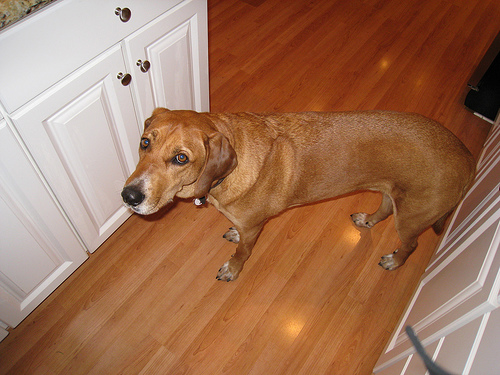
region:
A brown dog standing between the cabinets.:
[124, 105, 463, 285]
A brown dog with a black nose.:
[124, 105, 492, 289]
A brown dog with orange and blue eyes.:
[116, 105, 478, 287]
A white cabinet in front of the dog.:
[5, 22, 216, 251]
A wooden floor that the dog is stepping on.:
[220, 6, 453, 372]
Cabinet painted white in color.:
[1, 0, 237, 285]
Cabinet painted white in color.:
[412, 221, 495, 371]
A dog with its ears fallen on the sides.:
[124, 106, 466, 288]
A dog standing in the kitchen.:
[114, 104, 485, 294]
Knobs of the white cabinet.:
[100, 6, 156, 91]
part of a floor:
[280, 227, 333, 294]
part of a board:
[248, 265, 287, 324]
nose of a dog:
[118, 179, 148, 197]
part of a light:
[259, 280, 299, 360]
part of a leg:
[235, 210, 261, 252]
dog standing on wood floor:
[102, 89, 472, 309]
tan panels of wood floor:
[97, 247, 233, 369]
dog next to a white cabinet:
[90, 85, 248, 232]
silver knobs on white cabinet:
[100, 53, 165, 84]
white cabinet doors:
[40, 30, 244, 270]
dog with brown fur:
[103, 99, 490, 261]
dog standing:
[87, 72, 499, 348]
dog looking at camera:
[91, 83, 261, 233]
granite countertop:
[0, 4, 55, 17]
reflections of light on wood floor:
[242, 14, 457, 129]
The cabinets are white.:
[433, 243, 471, 345]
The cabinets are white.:
[411, 275, 480, 370]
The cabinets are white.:
[420, 257, 452, 355]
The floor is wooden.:
[193, 291, 274, 344]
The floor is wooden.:
[196, 306, 285, 362]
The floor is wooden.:
[159, 322, 261, 373]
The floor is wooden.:
[283, 335, 328, 368]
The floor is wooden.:
[219, 277, 319, 371]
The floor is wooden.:
[130, 293, 253, 365]